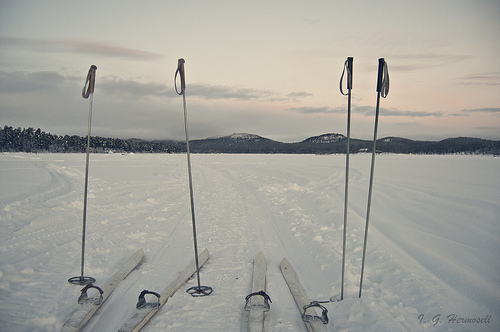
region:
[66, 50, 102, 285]
silver and black ski pole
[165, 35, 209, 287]
silver and black ski pole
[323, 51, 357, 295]
silver and black ski pole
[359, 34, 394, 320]
silver and black ski pole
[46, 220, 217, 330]
silver snow covered skis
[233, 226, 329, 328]
silver snow covered skis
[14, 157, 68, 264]
white snow with tracks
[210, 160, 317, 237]
white snow with tracks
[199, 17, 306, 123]
gray and pink clouds in sky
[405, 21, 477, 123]
gray and pink clouds in sky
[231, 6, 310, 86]
part of the sky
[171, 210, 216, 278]
part of a hooker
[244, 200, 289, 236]
part of a snow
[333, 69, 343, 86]
part of a belt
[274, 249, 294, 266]
tip of a skateboard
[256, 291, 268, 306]
part of a belt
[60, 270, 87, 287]
bottom of a hooker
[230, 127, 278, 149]
part of a mountain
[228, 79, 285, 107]
part of some clouds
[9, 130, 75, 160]
part of a forest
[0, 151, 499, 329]
Entire white snowy surface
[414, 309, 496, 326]
Faint name in the bottom right corner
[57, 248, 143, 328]
First ski on the left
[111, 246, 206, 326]
Second ski from the left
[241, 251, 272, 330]
Third ski from the left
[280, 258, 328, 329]
Last ski on the right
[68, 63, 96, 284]
First pole on the left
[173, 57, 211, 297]
Second pole from the left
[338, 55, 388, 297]
Two poles on the right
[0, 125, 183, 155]
Area in the background heavy with trees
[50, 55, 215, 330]
two ski poles are in the snow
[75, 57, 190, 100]
the ski poles have wrist holders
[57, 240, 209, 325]
the cross country skis are on the snow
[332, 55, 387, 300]
a pair of ski poles are standing in the snow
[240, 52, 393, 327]
the poles are next to cross country skis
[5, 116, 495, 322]
hills are on the horizon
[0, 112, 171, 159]
evergreen trees are on the horizon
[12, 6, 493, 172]
the sunset is orange with gray clouds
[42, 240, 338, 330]
two pairs of cross country skis are lying in the snow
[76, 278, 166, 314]
the binders on the skis are black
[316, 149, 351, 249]
part of a hooker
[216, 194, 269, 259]
part of some snow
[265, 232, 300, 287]
tip of a board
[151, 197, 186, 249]
part of some lines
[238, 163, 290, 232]
part of some foot tracks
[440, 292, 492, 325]
part of some writing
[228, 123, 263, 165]
part of a mountain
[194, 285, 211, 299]
bottom of a hooker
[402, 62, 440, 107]
part of the sky